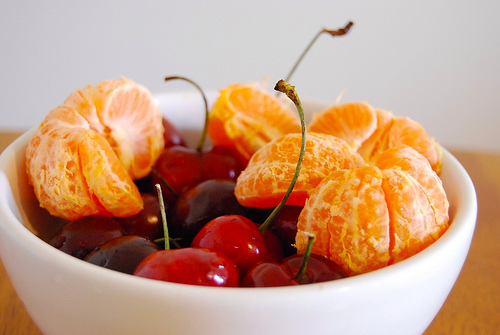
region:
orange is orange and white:
[12, 74, 144, 206]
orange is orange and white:
[286, 135, 406, 223]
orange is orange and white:
[291, 129, 456, 249]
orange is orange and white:
[231, 123, 326, 187]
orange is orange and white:
[286, 120, 413, 230]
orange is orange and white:
[291, 161, 434, 240]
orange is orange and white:
[240, 106, 371, 209]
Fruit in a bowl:
[19, 84, 472, 320]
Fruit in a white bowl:
[32, 79, 433, 318]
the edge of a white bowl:
[98, 256, 373, 318]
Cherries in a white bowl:
[27, 56, 418, 302]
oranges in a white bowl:
[217, 51, 458, 313]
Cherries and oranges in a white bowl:
[41, 82, 454, 324]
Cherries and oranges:
[46, 92, 433, 289]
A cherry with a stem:
[226, 75, 299, 268]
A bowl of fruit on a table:
[196, 66, 490, 326]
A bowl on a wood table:
[417, 219, 486, 334]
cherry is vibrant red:
[181, 195, 296, 292]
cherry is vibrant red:
[181, 215, 256, 272]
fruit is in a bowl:
[28, 22, 429, 331]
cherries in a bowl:
[31, 42, 475, 324]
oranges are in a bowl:
[21, 44, 497, 330]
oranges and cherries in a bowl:
[21, 31, 498, 333]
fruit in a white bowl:
[18, 52, 478, 329]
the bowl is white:
[14, 50, 466, 332]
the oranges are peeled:
[20, 45, 488, 297]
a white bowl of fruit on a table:
[15, 37, 467, 332]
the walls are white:
[26, 5, 495, 131]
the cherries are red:
[44, 70, 454, 334]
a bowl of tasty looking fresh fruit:
[1, 21, 479, 332]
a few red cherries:
[134, 218, 319, 277]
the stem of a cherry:
[271, 83, 312, 225]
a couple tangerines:
[266, 113, 448, 268]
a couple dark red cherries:
[60, 218, 148, 264]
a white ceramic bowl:
[31, 283, 451, 331]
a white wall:
[35, 12, 301, 74]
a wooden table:
[476, 168, 496, 319]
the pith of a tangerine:
[55, 145, 120, 200]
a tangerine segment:
[77, 129, 141, 216]